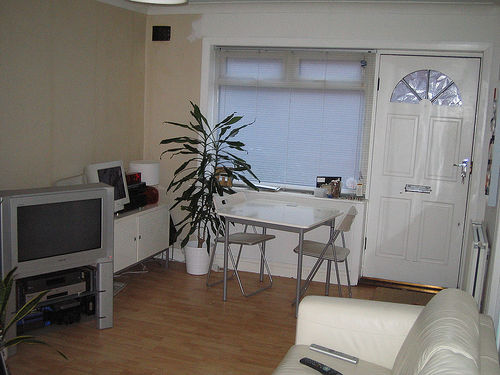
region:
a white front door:
[360, 44, 479, 291]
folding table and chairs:
[212, 188, 356, 304]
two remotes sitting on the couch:
[295, 340, 358, 373]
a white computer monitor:
[51, 161, 133, 211]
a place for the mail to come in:
[398, 177, 444, 202]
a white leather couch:
[272, 290, 498, 367]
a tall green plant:
[166, 97, 239, 282]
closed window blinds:
[209, 41, 368, 202]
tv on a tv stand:
[1, 185, 119, 335]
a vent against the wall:
[464, 215, 494, 312]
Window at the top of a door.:
[391, 71, 478, 121]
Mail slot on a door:
[396, 170, 447, 204]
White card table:
[209, 171, 345, 289]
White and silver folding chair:
[313, 201, 366, 298]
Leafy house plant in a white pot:
[159, 101, 236, 271]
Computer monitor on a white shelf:
[51, 154, 188, 278]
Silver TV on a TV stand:
[5, 186, 122, 308]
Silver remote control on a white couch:
[298, 333, 375, 363]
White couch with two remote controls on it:
[276, 281, 491, 373]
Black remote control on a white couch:
[286, 358, 347, 374]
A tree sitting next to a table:
[150, 94, 358, 311]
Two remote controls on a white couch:
[284, 329, 370, 374]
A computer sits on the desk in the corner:
[90, 155, 179, 264]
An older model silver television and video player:
[10, 182, 118, 334]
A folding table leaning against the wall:
[439, 204, 496, 305]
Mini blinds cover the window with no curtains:
[200, 42, 393, 202]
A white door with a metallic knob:
[354, 53, 499, 283]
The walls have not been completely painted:
[17, 7, 356, 123]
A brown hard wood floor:
[146, 284, 203, 374]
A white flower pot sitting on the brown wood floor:
[177, 237, 217, 279]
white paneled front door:
[371, 48, 478, 293]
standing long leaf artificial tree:
[161, 110, 238, 277]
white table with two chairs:
[216, 197, 358, 304]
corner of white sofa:
[290, 287, 476, 371]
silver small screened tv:
[3, 192, 115, 267]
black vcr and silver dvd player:
[18, 275, 101, 317]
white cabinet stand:
[117, 208, 179, 275]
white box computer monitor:
[55, 163, 134, 214]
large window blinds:
[204, 65, 371, 197]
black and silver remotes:
[298, 328, 368, 373]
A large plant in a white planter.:
[157, 102, 240, 277]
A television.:
[0, 186, 123, 269]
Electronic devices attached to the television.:
[19, 263, 111, 338]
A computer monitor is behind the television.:
[61, 153, 131, 213]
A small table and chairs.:
[212, 189, 354, 306]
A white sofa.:
[279, 277, 496, 374]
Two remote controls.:
[287, 335, 373, 374]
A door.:
[374, 40, 475, 285]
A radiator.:
[465, 217, 490, 300]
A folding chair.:
[291, 200, 359, 307]